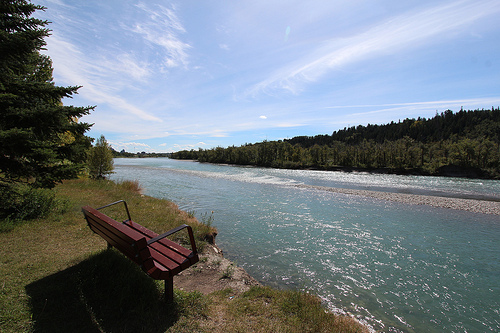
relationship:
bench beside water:
[80, 200, 201, 301] [102, 152, 497, 333]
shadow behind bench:
[23, 249, 179, 332] [80, 200, 201, 301]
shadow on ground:
[23, 249, 179, 332] [3, 175, 371, 332]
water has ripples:
[102, 152, 497, 333] [271, 168, 380, 183]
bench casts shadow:
[80, 200, 201, 301] [23, 249, 179, 332]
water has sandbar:
[102, 152, 497, 333] [290, 180, 499, 222]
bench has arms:
[80, 200, 201, 301] [146, 223, 199, 264]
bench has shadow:
[80, 200, 201, 301] [23, 249, 179, 332]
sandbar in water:
[290, 180, 499, 222] [102, 152, 497, 333]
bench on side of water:
[80, 200, 201, 301] [102, 152, 497, 333]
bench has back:
[80, 200, 201, 301] [81, 204, 154, 279]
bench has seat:
[80, 200, 201, 301] [122, 219, 199, 280]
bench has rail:
[80, 200, 201, 301] [90, 194, 132, 225]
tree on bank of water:
[1, 1, 98, 194] [102, 152, 497, 333]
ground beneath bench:
[3, 175, 371, 332] [80, 200, 201, 301]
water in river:
[102, 152, 497, 333] [104, 157, 499, 330]